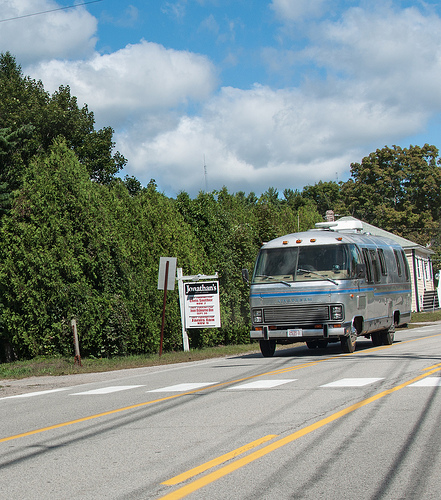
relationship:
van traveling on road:
[230, 204, 417, 365] [0, 315, 440, 498]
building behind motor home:
[407, 213, 435, 311] [239, 219, 414, 354]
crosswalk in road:
[0, 375, 440, 400] [0, 315, 440, 498]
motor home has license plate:
[216, 214, 432, 360] [278, 325, 309, 342]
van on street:
[230, 204, 417, 365] [0, 320, 440, 498]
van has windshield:
[230, 204, 417, 365] [252, 240, 356, 282]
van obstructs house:
[230, 204, 417, 365] [339, 188, 439, 328]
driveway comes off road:
[0, 374, 109, 426] [12, 353, 433, 492]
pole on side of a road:
[69, 314, 83, 363] [0, 315, 440, 498]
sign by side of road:
[183, 281, 221, 329] [0, 315, 440, 498]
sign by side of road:
[154, 252, 180, 291] [0, 315, 440, 498]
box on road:
[322, 375, 385, 388] [0, 315, 440, 498]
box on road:
[238, 371, 293, 391] [0, 315, 440, 498]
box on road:
[156, 374, 215, 393] [0, 315, 440, 498]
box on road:
[78, 379, 140, 398] [0, 315, 440, 498]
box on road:
[69, 385, 145, 396] [0, 315, 440, 498]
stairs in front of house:
[417, 287, 439, 308] [311, 204, 439, 316]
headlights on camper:
[331, 303, 343, 324] [244, 226, 410, 354]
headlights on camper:
[253, 308, 263, 325] [244, 226, 410, 354]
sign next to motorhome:
[178, 277, 222, 331] [246, 220, 414, 353]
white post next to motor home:
[173, 266, 220, 349] [239, 219, 414, 354]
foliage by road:
[3, 48, 439, 351] [0, 315, 440, 498]